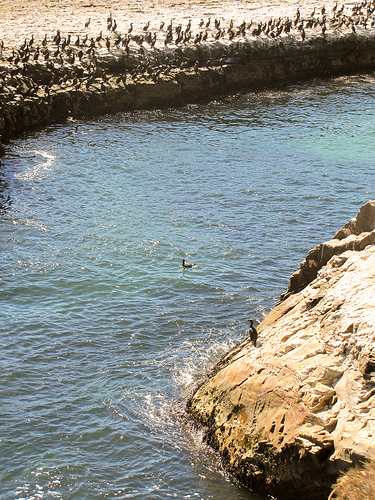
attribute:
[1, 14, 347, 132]
ledge — long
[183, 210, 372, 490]
rocks — light brown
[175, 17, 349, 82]
cliff — jagged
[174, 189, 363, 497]
ledge — tall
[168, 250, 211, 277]
duck — small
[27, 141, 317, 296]
water — dark blue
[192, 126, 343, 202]
water — choppy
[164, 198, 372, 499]
ledge — rocky, light brown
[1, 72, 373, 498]
water — running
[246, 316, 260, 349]
bird — black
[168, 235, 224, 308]
birds — edge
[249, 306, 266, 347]
birds — one , itself 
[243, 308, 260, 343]
bird — one 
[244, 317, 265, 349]
bird — line 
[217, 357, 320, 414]
rock — side 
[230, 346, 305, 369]
rock — small 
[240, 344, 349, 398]
rock — edge 